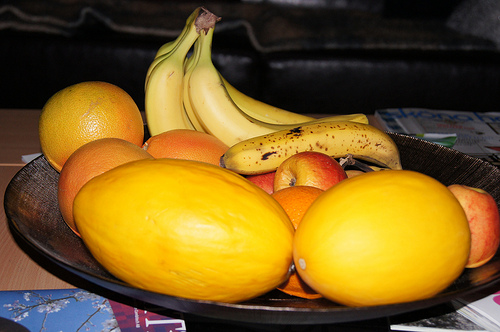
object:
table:
[1, 108, 37, 157]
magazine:
[370, 106, 495, 159]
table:
[0, 108, 500, 332]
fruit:
[36, 80, 144, 173]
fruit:
[72, 156, 295, 303]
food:
[71, 159, 299, 304]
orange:
[38, 80, 143, 174]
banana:
[144, 26, 204, 137]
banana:
[182, 26, 370, 153]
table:
[1, 106, 22, 164]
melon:
[291, 169, 472, 309]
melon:
[71, 156, 298, 302]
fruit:
[36, 5, 500, 308]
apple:
[273, 150, 349, 191]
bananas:
[215, 67, 317, 125]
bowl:
[4, 129, 500, 326]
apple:
[446, 184, 499, 268]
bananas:
[142, 56, 185, 136]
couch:
[0, 0, 500, 112]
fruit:
[290, 169, 470, 309]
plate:
[0, 130, 500, 328]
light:
[67, 156, 295, 296]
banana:
[219, 121, 404, 175]